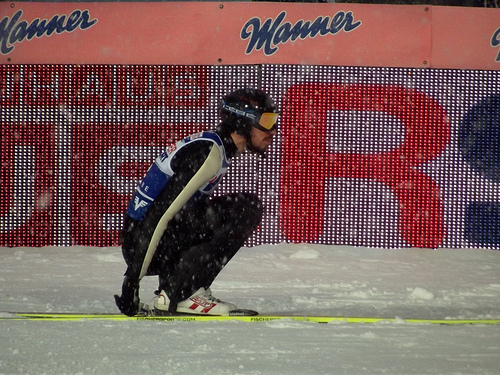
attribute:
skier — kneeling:
[100, 84, 280, 312]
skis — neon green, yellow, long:
[2, 306, 500, 329]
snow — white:
[7, 248, 500, 362]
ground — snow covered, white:
[7, 247, 495, 366]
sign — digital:
[3, 67, 499, 247]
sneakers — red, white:
[156, 288, 237, 314]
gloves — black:
[113, 274, 145, 315]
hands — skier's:
[113, 272, 141, 314]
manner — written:
[237, 10, 364, 61]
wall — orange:
[7, 8, 499, 245]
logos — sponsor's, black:
[3, 1, 500, 52]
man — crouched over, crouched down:
[101, 86, 279, 314]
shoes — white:
[149, 285, 233, 313]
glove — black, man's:
[112, 274, 144, 316]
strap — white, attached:
[222, 100, 256, 117]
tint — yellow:
[263, 113, 280, 129]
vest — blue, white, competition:
[122, 127, 229, 218]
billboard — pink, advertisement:
[0, 5, 499, 243]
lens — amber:
[260, 110, 279, 131]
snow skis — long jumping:
[4, 310, 500, 326]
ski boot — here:
[152, 290, 234, 312]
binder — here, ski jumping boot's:
[167, 244, 203, 312]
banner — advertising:
[2, 6, 499, 67]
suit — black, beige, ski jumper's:
[122, 129, 253, 299]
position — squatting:
[103, 85, 293, 311]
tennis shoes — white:
[149, 285, 233, 317]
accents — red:
[189, 293, 218, 315]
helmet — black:
[213, 81, 279, 128]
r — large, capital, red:
[275, 76, 455, 239]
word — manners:
[243, 1, 357, 55]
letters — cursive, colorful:
[236, 4, 365, 62]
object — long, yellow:
[11, 305, 499, 331]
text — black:
[16, 316, 442, 322]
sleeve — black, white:
[129, 141, 225, 287]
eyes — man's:
[262, 119, 283, 134]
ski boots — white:
[168, 285, 236, 315]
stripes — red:
[188, 295, 221, 314]